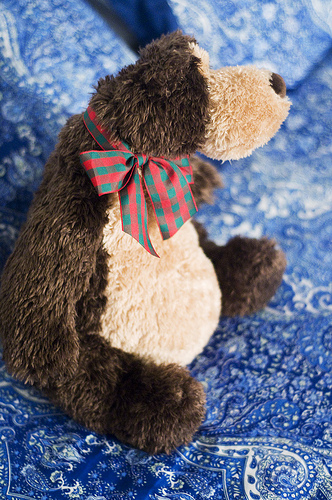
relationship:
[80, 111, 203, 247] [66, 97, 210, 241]
bow around neck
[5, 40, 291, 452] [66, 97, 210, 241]
teddy bear has neck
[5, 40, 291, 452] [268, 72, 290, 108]
teddy bear has nose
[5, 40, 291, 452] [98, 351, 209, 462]
teddy bear has right foot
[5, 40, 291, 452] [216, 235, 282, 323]
teddy bear has left foot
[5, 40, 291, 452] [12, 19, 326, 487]
teddy bear sitting on bedspread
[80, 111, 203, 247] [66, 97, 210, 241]
bow tied around neck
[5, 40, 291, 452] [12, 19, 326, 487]
teddy bear on bedspread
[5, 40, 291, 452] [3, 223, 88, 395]
teddy bear has right arm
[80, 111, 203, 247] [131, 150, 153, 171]
bow has knot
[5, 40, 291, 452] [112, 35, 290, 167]
teddy bear has head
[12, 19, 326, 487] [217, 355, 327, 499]
bedspread has design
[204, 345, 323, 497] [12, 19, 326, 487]
paisley printed on bedspread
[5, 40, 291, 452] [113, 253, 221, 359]
teddy bear has tummy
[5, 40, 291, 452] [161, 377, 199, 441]
teddy bear has paw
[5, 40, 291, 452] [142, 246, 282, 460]
teddy bear has leg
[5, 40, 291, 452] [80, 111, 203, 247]
teddy bear has bow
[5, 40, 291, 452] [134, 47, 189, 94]
teddy bear has ear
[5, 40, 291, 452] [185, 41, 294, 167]
teddy bear has face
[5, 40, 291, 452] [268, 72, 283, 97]
teddy bear has nose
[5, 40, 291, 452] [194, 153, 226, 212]
teddy bear has left arm